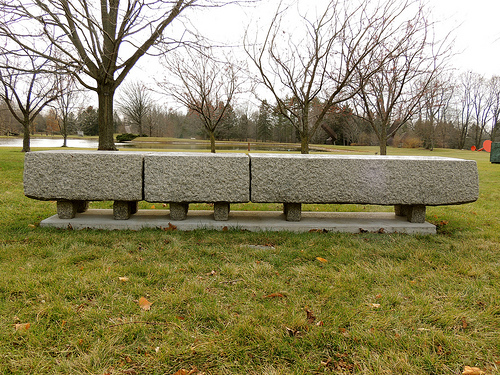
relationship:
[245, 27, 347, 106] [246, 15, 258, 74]
branches in sky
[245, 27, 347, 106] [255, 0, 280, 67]
branches in sky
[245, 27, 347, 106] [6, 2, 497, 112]
branches in sky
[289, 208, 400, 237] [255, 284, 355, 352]
shadow on ground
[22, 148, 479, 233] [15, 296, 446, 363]
stone on ground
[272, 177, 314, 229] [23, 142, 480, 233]
leg on block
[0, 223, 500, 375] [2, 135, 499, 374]
leaf on grass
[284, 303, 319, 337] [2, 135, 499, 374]
leaf on grass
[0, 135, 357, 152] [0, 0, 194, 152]
water by trees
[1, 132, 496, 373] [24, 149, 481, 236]
field beneath stone design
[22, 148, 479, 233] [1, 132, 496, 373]
stone in field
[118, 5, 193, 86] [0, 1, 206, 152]
branch on tree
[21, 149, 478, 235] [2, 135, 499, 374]
concrete on grass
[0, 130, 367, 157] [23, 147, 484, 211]
water behind concrete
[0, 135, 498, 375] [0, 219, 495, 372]
grass in field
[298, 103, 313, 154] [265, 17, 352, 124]
treetrunk on tree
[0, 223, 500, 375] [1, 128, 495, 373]
leaf on ground